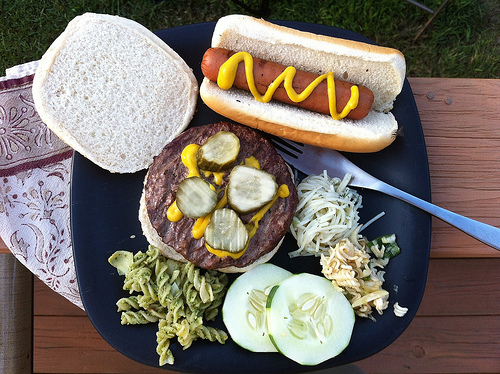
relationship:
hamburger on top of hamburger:
[146, 123, 298, 269] [146, 123, 298, 269]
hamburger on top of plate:
[146, 123, 298, 269] [70, 22, 431, 374]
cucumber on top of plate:
[266, 274, 354, 365] [70, 22, 431, 374]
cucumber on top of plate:
[222, 263, 295, 353] [70, 22, 431, 374]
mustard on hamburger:
[168, 145, 290, 259] [146, 123, 298, 269]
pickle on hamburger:
[228, 166, 276, 212] [146, 123, 298, 269]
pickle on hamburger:
[198, 133, 237, 171] [146, 123, 298, 269]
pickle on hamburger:
[174, 178, 216, 218] [146, 123, 298, 269]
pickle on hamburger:
[204, 209, 249, 253] [146, 123, 298, 269]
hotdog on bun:
[198, 47, 373, 121] [200, 14, 405, 157]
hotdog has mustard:
[198, 47, 373, 121] [216, 51, 358, 119]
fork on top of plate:
[269, 138, 499, 250] [70, 22, 431, 374]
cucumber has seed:
[266, 274, 354, 365] [302, 296, 315, 311]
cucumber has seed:
[266, 274, 354, 365] [286, 326, 305, 338]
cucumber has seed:
[266, 274, 354, 365] [324, 317, 332, 334]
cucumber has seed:
[266, 274, 354, 365] [317, 324, 323, 335]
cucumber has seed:
[266, 274, 354, 365] [313, 301, 325, 319]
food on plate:
[319, 235, 408, 321] [70, 22, 431, 374]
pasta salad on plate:
[109, 245, 228, 366] [70, 22, 431, 374]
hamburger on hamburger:
[146, 123, 298, 269] [146, 123, 298, 269]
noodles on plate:
[287, 170, 385, 256] [70, 22, 431, 374]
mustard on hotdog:
[216, 51, 358, 119] [198, 47, 373, 121]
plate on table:
[70, 22, 431, 374] [31, 78, 498, 373]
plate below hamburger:
[70, 22, 431, 374] [146, 123, 298, 269]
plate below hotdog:
[70, 22, 431, 374] [198, 47, 373, 121]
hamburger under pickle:
[146, 123, 298, 269] [198, 133, 237, 171]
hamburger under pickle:
[146, 123, 298, 269] [204, 209, 249, 253]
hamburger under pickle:
[146, 123, 298, 269] [174, 178, 216, 218]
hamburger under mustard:
[146, 123, 298, 269] [168, 145, 290, 259]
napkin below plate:
[0, 59, 87, 312] [70, 22, 431, 374]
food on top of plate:
[319, 235, 408, 321] [70, 22, 431, 374]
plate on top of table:
[70, 22, 431, 374] [31, 78, 498, 373]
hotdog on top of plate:
[198, 47, 373, 121] [70, 22, 431, 374]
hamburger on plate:
[146, 123, 298, 269] [70, 22, 431, 374]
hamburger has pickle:
[146, 123, 298, 269] [198, 133, 237, 171]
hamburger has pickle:
[146, 123, 298, 269] [204, 209, 249, 253]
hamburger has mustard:
[146, 123, 298, 269] [168, 145, 290, 259]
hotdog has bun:
[198, 47, 373, 121] [200, 14, 405, 157]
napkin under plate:
[0, 59, 87, 312] [70, 22, 431, 374]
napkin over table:
[0, 59, 87, 312] [31, 78, 498, 373]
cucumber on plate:
[266, 274, 354, 365] [70, 22, 431, 374]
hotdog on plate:
[198, 47, 373, 121] [70, 22, 431, 374]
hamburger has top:
[146, 123, 298, 269] [32, 13, 198, 174]